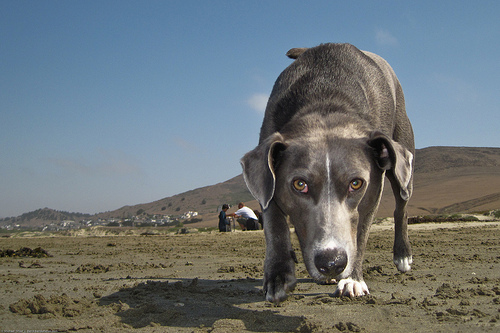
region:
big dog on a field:
[232, 39, 423, 306]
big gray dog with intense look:
[244, 45, 415, 309]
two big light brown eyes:
[295, 176, 363, 200]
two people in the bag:
[215, 202, 262, 226]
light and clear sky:
[1, 5, 498, 213]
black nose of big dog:
[318, 249, 350, 280]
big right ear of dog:
[235, 131, 286, 206]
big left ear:
[364, 133, 415, 190]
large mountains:
[7, 138, 498, 218]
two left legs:
[335, 139, 410, 297]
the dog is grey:
[248, 40, 433, 301]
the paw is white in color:
[338, 270, 372, 300]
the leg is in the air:
[238, 215, 305, 312]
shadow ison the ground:
[151, 271, 243, 331]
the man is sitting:
[232, 198, 268, 241]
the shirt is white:
[236, 206, 258, 218]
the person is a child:
[211, 201, 236, 237]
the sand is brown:
[16, 233, 203, 331]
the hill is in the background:
[425, 141, 498, 221]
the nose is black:
[309, 250, 353, 282]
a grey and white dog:
[239, 40, 415, 301]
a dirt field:
[0, 226, 498, 331]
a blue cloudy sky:
[1, 0, 496, 217]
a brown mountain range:
[0, 145, 499, 227]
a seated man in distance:
[224, 203, 258, 228]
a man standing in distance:
[215, 201, 230, 231]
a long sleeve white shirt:
[231, 205, 253, 219]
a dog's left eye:
[344, 175, 364, 194]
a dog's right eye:
[291, 175, 310, 195]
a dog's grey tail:
[282, 46, 304, 58]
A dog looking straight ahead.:
[248, 41, 411, 311]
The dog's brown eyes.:
[291, 175, 365, 197]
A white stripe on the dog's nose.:
[322, 152, 335, 251]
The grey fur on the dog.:
[302, 60, 367, 112]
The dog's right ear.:
[243, 134, 285, 207]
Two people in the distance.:
[218, 203, 260, 235]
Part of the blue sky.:
[49, 55, 135, 99]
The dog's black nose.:
[313, 246, 345, 278]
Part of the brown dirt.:
[106, 244, 187, 282]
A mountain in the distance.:
[3, 205, 88, 225]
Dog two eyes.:
[292, 178, 360, 194]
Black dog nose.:
[314, 252, 345, 274]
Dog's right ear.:
[372, 130, 412, 200]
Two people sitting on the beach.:
[219, 202, 261, 232]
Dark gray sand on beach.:
[22, 239, 179, 311]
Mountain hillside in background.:
[24, 208, 98, 233]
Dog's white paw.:
[335, 282, 369, 297]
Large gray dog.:
[237, 44, 414, 304]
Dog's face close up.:
[277, 144, 384, 285]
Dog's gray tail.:
[286, 44, 309, 58]